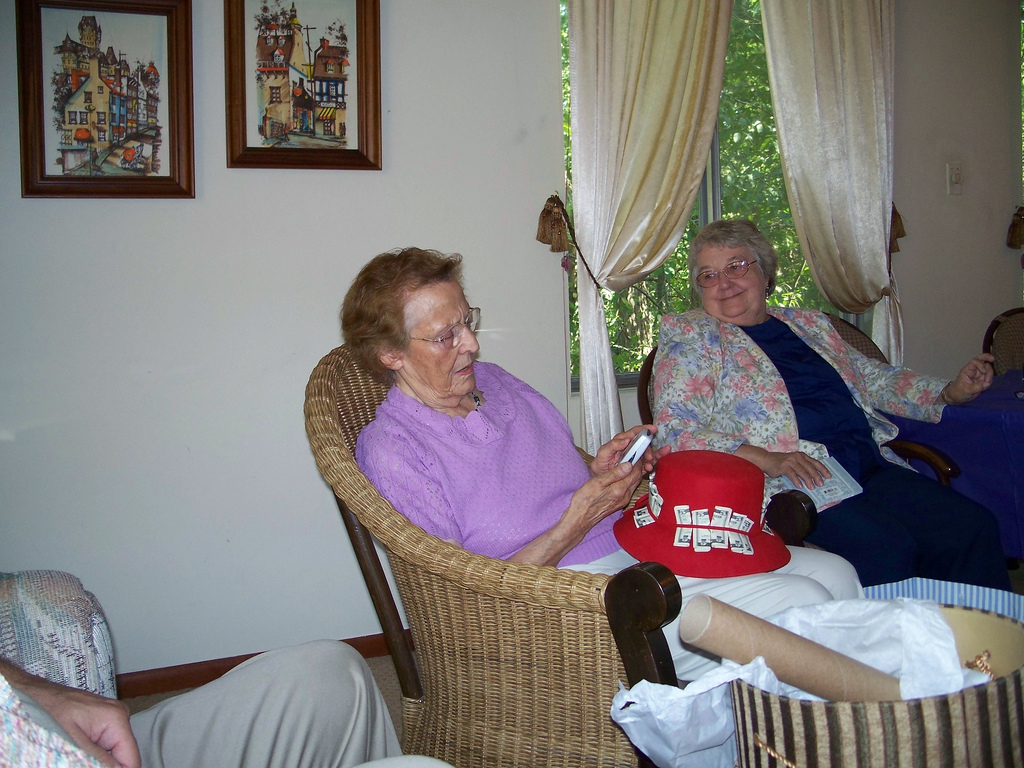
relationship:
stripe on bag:
[734, 685, 766, 767] [732, 660, 1023, 765]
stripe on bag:
[734, 685, 766, 767] [691, 575, 1008, 765]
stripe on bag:
[734, 685, 766, 767] [707, 605, 1012, 754]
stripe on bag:
[734, 685, 766, 767] [738, 572, 1023, 763]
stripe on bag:
[734, 685, 766, 767] [729, 594, 1023, 763]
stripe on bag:
[841, 685, 874, 763] [729, 594, 1023, 763]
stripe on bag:
[734, 685, 766, 767] [738, 588, 1008, 765]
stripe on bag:
[734, 685, 766, 767] [727, 588, 1013, 753]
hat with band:
[628, 442, 818, 567] [674, 503, 754, 553]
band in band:
[674, 503, 754, 553] [681, 512, 759, 552]